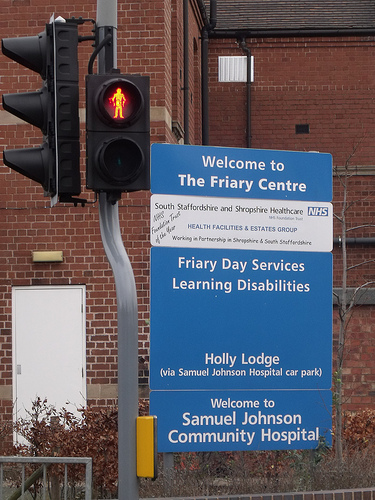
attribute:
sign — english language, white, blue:
[146, 144, 340, 461]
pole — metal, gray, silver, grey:
[94, 189, 147, 499]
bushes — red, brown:
[19, 392, 370, 500]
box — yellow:
[135, 413, 162, 486]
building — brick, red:
[2, 3, 373, 460]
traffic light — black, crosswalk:
[88, 69, 149, 190]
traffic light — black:
[8, 9, 83, 209]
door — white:
[11, 284, 86, 444]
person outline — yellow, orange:
[109, 85, 130, 119]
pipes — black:
[69, 10, 101, 209]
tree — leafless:
[325, 146, 374, 470]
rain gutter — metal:
[200, 30, 213, 147]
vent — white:
[216, 56, 255, 84]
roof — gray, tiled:
[200, 3, 374, 36]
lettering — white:
[159, 146, 323, 446]